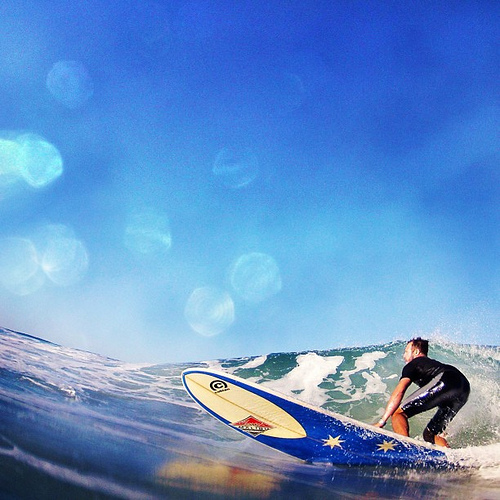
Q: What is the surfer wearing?
A: A wet suit.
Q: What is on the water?
A: White foam.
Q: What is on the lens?
A: Water.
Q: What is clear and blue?
A: The sky.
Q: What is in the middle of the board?
A: A yellow line.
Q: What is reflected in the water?
A: The surfboard.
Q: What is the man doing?
A: Surfing.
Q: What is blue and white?
A: The surfboard.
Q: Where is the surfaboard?
A: Water.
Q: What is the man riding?
A: Surfboard.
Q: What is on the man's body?
A: Wet suit.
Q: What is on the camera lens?
A: Water.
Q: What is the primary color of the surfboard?
A: Blue.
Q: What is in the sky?
A: Clouds.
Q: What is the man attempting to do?
A: Surf.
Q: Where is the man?
A: Ocean.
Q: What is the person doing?
A: Surfing.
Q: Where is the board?
A: In the water.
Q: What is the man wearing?
A: Wetsuit.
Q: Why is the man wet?
A: He is in the water.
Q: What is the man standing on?
A: Surfboard.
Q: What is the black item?
A: The wetsuit.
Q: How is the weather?
A: Sunny and clear.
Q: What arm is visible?
A: The surfer's left arm.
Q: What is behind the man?
A: Waves.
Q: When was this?
A: Daytime.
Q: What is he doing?
A: Surfing.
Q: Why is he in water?
A: To surf.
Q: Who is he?
A: A surfer.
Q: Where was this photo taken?
A: In the ocean.